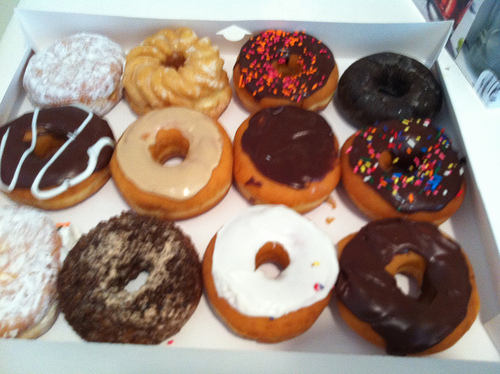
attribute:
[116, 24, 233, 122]
donut — glaze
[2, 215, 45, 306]
sugar — powdered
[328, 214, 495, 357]
donut — round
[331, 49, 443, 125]
donut — round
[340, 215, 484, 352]
donut — round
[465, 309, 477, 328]
doughnut — chocolate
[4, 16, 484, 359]
donuts — fresh, dozen, one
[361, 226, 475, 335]
frosting — chocolate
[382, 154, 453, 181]
sprinkles — red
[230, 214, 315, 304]
frosting — white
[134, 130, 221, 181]
frosting — maple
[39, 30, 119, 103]
powder — sugar, confectioner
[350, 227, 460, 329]
frosted — chocolate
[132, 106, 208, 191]
frosting — maple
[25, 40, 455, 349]
doughnuts — one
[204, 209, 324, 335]
icing — white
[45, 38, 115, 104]
doughnut — filled